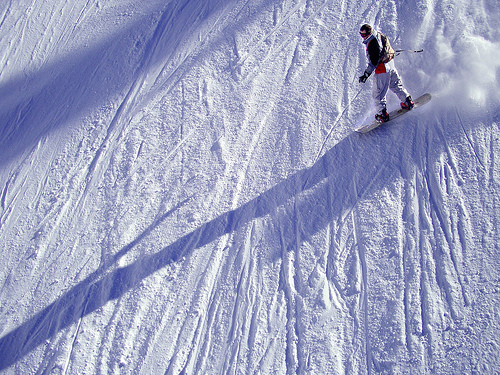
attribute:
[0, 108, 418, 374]
shadow — here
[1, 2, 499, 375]
snow — fluffy, here, white, fresh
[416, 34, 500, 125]
dust — white, snowy, cloudlike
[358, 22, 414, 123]
snowboarder — snowboarding, skiing, here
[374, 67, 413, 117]
pants — white, gray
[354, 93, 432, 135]
snowboard — here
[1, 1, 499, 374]
hill — here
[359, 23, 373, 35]
hair — brown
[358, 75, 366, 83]
glove — black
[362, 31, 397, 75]
coat — black, grey